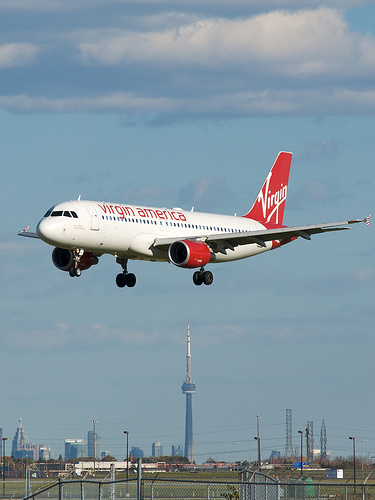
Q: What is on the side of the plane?
A: The wing.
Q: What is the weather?
A: Partly cloudy.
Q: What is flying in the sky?
A: Airplane.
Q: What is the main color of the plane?
A: White.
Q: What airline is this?
A: Virgin airlines.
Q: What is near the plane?
A: A metal fence.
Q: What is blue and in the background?
A: The sky.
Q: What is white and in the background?
A: The clouds.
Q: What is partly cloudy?
A: The sky.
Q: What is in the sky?
A: The airplane.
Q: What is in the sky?
A: The airplane.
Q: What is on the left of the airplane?
A: The wing.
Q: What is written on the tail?
A: Virgin.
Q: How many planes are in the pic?
A: 1.